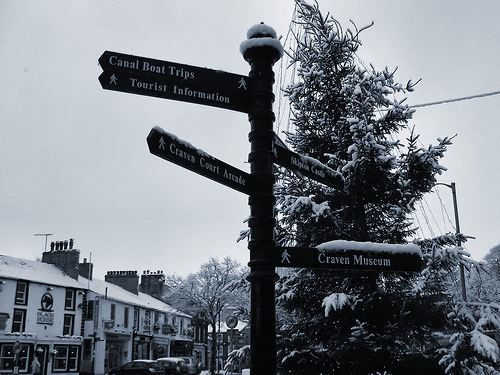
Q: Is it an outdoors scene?
A: Yes, it is outdoors.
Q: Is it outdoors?
A: Yes, it is outdoors.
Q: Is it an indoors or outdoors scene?
A: It is outdoors.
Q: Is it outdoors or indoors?
A: It is outdoors.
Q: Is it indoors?
A: No, it is outdoors.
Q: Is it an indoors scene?
A: No, it is outdoors.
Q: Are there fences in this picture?
A: No, there are no fences.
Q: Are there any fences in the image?
A: No, there are no fences.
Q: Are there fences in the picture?
A: No, there are no fences.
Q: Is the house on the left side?
A: Yes, the house is on the left of the image.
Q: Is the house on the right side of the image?
A: No, the house is on the left of the image.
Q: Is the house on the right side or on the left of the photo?
A: The house is on the left of the image.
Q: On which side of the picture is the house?
A: The house is on the left of the image.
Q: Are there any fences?
A: No, there are no fences.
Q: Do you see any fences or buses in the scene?
A: No, there are no fences or buses.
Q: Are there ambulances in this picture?
A: No, there are no ambulances.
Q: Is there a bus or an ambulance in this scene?
A: No, there are no ambulances or buses.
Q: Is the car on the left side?
A: Yes, the car is on the left of the image.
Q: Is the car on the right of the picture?
A: No, the car is on the left of the image.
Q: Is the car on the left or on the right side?
A: The car is on the left of the image.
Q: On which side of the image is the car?
A: The car is on the left of the image.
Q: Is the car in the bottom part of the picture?
A: Yes, the car is in the bottom of the image.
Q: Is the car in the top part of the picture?
A: No, the car is in the bottom of the image.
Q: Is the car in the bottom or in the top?
A: The car is in the bottom of the image.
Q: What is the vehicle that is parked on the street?
A: The vehicle is a car.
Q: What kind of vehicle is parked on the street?
A: The vehicle is a car.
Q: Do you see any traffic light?
A: No, there are no traffic lights.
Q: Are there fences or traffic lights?
A: No, there are no traffic lights or fences.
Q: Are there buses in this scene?
A: No, there are no buses.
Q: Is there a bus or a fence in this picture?
A: No, there are no buses or fences.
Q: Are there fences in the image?
A: No, there are no fences.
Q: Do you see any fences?
A: No, there are no fences.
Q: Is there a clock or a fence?
A: No, there are no fences or clocks.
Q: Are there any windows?
A: Yes, there is a window.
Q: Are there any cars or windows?
A: Yes, there is a window.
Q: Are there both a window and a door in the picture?
A: Yes, there are both a window and a door.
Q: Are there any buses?
A: No, there are no buses.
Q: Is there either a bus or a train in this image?
A: No, there are no buses or trains.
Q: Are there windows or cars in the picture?
A: Yes, there is a window.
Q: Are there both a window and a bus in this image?
A: No, there is a window but no buses.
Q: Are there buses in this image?
A: No, there are no buses.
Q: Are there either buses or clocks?
A: No, there are no buses or clocks.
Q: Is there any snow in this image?
A: Yes, there is snow.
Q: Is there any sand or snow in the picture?
A: Yes, there is snow.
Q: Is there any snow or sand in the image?
A: Yes, there is snow.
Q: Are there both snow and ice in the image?
A: No, there is snow but no ice.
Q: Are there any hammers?
A: No, there are no hammers.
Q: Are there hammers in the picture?
A: No, there are no hammers.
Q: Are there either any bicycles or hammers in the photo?
A: No, there are no hammers or bicycles.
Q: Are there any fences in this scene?
A: No, there are no fences.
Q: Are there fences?
A: No, there are no fences.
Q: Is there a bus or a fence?
A: No, there are no fences or buses.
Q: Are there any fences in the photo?
A: No, there are no fences.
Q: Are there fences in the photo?
A: No, there are no fences.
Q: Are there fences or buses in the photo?
A: No, there are no fences or buses.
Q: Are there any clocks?
A: No, there are no clocks.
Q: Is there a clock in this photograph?
A: No, there are no clocks.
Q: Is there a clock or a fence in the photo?
A: No, there are no clocks or fences.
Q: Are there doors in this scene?
A: Yes, there is a door.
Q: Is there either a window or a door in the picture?
A: Yes, there is a door.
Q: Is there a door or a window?
A: Yes, there is a door.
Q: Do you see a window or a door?
A: Yes, there is a door.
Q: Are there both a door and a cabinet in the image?
A: No, there is a door but no cabinets.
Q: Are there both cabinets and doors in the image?
A: No, there is a door but no cabinets.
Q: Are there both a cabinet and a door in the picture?
A: No, there is a door but no cabinets.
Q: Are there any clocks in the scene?
A: No, there are no clocks.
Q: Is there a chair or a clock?
A: No, there are no clocks or chairs.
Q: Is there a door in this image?
A: Yes, there is a door.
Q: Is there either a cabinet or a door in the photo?
A: Yes, there is a door.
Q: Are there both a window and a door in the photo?
A: Yes, there are both a door and a window.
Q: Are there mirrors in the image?
A: No, there are no mirrors.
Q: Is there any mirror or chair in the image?
A: No, there are no mirrors or chairs.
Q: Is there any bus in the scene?
A: No, there are no buses.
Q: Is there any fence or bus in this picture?
A: No, there are no buses or fences.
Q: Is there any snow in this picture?
A: Yes, there is snow.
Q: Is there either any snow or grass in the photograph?
A: Yes, there is snow.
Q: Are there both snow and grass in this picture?
A: No, there is snow but no grass.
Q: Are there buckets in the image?
A: No, there are no buckets.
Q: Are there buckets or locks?
A: No, there are no buckets or locks.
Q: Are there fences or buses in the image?
A: No, there are no fences or buses.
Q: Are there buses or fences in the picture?
A: No, there are no fences or buses.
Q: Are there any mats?
A: No, there are no mats.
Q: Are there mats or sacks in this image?
A: No, there are no mats or sacks.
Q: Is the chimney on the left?
A: Yes, the chimney is on the left of the image.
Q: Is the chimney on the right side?
A: No, the chimney is on the left of the image.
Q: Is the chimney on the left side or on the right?
A: The chimney is on the left of the image.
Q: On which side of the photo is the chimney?
A: The chimney is on the left of the image.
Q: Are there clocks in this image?
A: No, there are no clocks.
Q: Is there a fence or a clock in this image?
A: No, there are no clocks or fences.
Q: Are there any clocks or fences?
A: No, there are no clocks or fences.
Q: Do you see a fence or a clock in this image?
A: No, there are no clocks or fences.